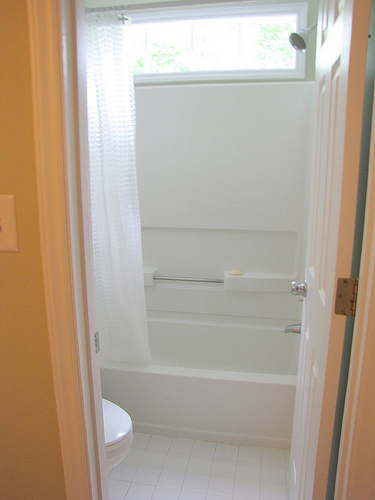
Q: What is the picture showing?
A: It is showing a bathroom.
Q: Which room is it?
A: It is a bathroom.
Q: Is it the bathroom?
A: Yes, it is the bathroom.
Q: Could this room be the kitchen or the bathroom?
A: It is the bathroom.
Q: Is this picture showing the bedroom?
A: No, the picture is showing the bathroom.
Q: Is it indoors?
A: Yes, it is indoors.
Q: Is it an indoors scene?
A: Yes, it is indoors.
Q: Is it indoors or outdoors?
A: It is indoors.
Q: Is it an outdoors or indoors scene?
A: It is indoors.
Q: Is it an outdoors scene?
A: No, it is indoors.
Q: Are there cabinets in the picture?
A: No, there are no cabinets.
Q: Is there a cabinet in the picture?
A: No, there are no cabinets.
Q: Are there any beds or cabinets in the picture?
A: No, there are no cabinets or beds.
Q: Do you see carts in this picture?
A: No, there are no carts.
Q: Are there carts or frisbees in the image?
A: No, there are no carts or frisbees.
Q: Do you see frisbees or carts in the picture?
A: No, there are no carts or frisbees.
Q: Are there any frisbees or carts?
A: No, there are no carts or frisbees.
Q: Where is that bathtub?
A: The bathtub is in the bathroom.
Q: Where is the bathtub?
A: The bathtub is in the bathroom.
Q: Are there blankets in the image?
A: No, there are no blankets.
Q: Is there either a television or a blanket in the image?
A: No, there are no blankets or televisions.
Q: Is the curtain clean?
A: Yes, the curtain is clean.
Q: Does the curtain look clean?
A: Yes, the curtain is clean.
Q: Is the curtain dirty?
A: No, the curtain is clean.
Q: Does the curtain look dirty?
A: No, the curtain is clean.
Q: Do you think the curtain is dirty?
A: No, the curtain is clean.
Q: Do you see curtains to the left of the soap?
A: Yes, there is a curtain to the left of the soap.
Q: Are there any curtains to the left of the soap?
A: Yes, there is a curtain to the left of the soap.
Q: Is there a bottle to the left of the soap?
A: No, there is a curtain to the left of the soap.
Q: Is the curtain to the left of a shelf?
A: No, the curtain is to the left of a soap.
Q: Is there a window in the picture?
A: Yes, there is a window.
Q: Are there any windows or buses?
A: Yes, there is a window.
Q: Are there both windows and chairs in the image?
A: No, there is a window but no chairs.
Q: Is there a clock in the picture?
A: No, there are no clocks.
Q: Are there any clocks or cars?
A: No, there are no clocks or cars.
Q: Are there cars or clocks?
A: No, there are no clocks or cars.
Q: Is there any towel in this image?
A: No, there are no towels.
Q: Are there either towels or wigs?
A: No, there are no towels or wigs.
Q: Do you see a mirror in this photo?
A: No, there are no mirrors.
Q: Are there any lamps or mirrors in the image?
A: No, there are no mirrors or lamps.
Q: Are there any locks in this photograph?
A: No, there are no locks.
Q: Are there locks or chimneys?
A: No, there are no locks or chimneys.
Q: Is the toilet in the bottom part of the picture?
A: Yes, the toilet is in the bottom of the image.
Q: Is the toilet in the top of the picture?
A: No, the toilet is in the bottom of the image.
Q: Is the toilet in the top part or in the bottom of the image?
A: The toilet is in the bottom of the image.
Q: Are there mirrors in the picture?
A: No, there are no mirrors.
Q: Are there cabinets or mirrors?
A: No, there are no mirrors or cabinets.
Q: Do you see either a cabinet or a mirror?
A: No, there are no mirrors or cabinets.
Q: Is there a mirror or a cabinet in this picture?
A: No, there are no mirrors or cabinets.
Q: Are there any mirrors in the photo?
A: No, there are no mirrors.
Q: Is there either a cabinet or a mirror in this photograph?
A: No, there are no mirrors or cabinets.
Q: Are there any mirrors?
A: No, there are no mirrors.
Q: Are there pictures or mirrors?
A: No, there are no mirrors or pictures.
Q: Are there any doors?
A: Yes, there is a door.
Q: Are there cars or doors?
A: Yes, there is a door.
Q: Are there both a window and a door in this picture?
A: Yes, there are both a door and a window.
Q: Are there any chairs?
A: No, there are no chairs.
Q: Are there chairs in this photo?
A: No, there are no chairs.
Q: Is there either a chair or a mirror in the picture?
A: No, there are no chairs or mirrors.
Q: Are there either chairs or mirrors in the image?
A: No, there are no chairs or mirrors.